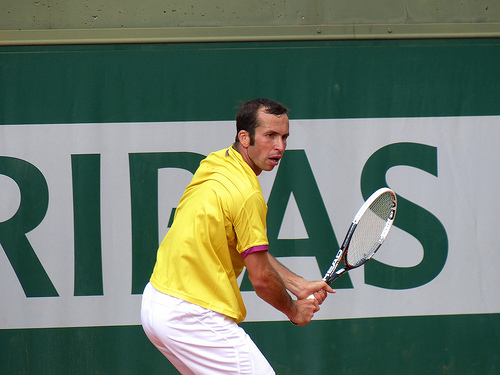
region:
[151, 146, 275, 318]
the man is wearing a t shirt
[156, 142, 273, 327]
the shirt is yellow in color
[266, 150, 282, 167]
the man has his mouth opened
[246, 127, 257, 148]
the man has long side burns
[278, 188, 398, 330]
the man is holding a racket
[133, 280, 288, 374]
the pants are white in color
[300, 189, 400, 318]
the racket is for tennis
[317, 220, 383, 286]
the racket is part black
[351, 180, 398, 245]
the racket is part white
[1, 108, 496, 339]
a sign is behind the player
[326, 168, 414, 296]
black and white tennis racquet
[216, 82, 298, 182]
tennis player with brown hair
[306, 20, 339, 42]
beige bolt securing sign to wall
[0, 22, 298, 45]
beige metal sign trim on wall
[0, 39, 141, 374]
large green and white sign on wall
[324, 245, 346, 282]
writing on handle of tennis racquet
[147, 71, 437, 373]
tennis player preparing to hit ball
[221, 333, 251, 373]
white seam on side of tennis shorts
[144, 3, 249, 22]
small holes in stone wall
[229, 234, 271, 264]
pink sleeve on shirt of tennis player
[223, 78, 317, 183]
a man with short hair.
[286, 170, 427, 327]
a tennis racket.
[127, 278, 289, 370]
a pair of white shorts.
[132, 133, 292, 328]
a yellow shirt.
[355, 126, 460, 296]
a large S on a wall.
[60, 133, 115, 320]
a large I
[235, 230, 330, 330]
a right human arm.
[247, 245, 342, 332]
a left human arm.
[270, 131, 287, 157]
a nose on a face.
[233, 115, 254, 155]
a right human ear.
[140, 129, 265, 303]
The man has a yellow shirt.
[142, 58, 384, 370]
The man is focused.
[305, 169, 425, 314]
This is a tennis racket.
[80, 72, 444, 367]
The man is playing tennis.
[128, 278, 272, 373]
The man's shorts are white.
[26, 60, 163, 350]
The banner is green and white.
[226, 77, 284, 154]
The man has brown hair.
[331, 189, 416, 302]
the racket is black and white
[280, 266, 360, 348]
the man is holding the racket with both hands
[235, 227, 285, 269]
The edge of his shirt is pink.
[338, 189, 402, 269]
a tennis racket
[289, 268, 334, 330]
tennis player holding a tennis racket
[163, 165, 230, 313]
yellow shirt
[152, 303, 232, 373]
white shorts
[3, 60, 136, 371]
banner is green and white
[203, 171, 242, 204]
wrinkles in the shirt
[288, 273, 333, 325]
both hands on the racket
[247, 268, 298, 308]
tennis players arm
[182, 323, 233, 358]
wrinkles in shorts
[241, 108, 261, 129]
black hair